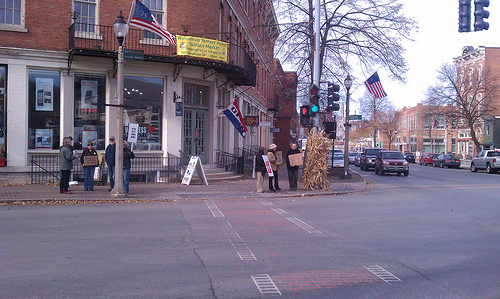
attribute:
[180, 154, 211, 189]
sign — sandwich board]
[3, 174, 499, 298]
street — grey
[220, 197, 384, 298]
crosswalk — red brick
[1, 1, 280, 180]
building — brick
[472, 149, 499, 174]
car — parked, silver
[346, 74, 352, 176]
lamppost — silver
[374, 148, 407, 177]
car — red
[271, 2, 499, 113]
sky — clear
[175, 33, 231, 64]
banner — yellow, green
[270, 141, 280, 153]
cap — bone colored